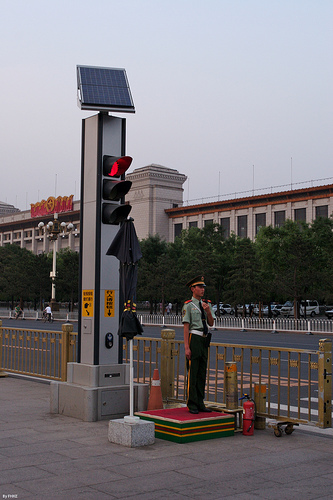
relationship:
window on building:
[233, 212, 249, 238] [134, 162, 330, 254]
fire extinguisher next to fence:
[239, 393, 257, 436] [0, 314, 333, 429]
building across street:
[0, 163, 333, 258] [2, 317, 330, 407]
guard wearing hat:
[181, 269, 218, 414] [185, 271, 206, 290]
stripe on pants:
[183, 329, 197, 403] [184, 330, 216, 414]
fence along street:
[0, 314, 333, 429] [0, 311, 331, 419]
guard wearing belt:
[181, 269, 218, 414] [184, 328, 209, 338]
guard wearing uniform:
[181, 269, 218, 414] [178, 294, 212, 402]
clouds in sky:
[0, 0, 332, 210] [0, 1, 333, 212]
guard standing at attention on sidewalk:
[181, 269, 218, 414] [3, 370, 316, 491]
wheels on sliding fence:
[267, 422, 298, 436] [0, 314, 333, 429]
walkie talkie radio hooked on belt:
[205, 333, 217, 347] [186, 326, 213, 335]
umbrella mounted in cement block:
[106, 216, 145, 343] [105, 412, 156, 447]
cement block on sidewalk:
[105, 412, 156, 447] [3, 374, 332, 497]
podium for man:
[136, 405, 244, 446] [183, 277, 210, 421]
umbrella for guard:
[106, 216, 145, 421] [170, 271, 224, 414]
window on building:
[229, 211, 251, 242] [182, 188, 317, 232]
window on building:
[274, 210, 286, 226] [0, 177, 333, 265]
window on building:
[235, 215, 247, 240] [0, 177, 333, 265]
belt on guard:
[186, 324, 209, 340] [177, 269, 219, 414]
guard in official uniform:
[181, 269, 218, 414] [180, 273, 215, 410]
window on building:
[275, 210, 285, 226] [0, 176, 332, 310]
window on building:
[173, 210, 223, 237] [19, 129, 332, 340]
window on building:
[292, 207, 305, 218] [0, 163, 333, 258]